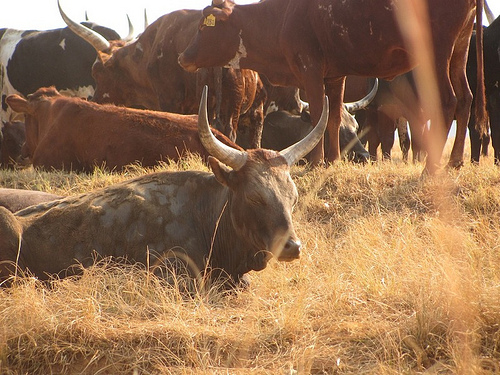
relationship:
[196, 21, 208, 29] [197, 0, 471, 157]
eye of cow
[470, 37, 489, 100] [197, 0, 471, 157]
tail of cow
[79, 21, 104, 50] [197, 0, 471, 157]
horn on cow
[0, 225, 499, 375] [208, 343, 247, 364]
ground on ground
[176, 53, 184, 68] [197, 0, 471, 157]
nose of cow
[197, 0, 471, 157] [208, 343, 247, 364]
cow on ground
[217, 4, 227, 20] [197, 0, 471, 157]
ear of cow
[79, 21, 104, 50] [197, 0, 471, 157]
horn of cow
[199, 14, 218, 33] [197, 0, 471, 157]
tag on cow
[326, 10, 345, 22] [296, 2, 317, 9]
spots on back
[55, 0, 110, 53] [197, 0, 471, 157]
horn of cow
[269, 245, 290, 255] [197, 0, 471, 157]
mouth of cow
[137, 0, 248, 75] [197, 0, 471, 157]
head of cow